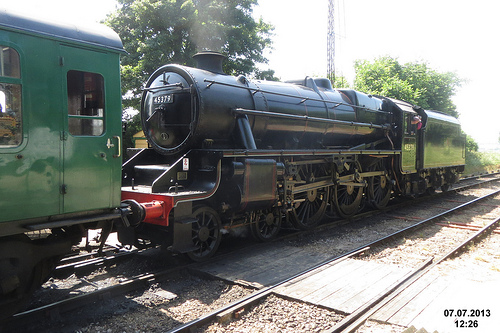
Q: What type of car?
A: Train.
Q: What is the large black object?
A: The train engine.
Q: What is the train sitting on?
A: A long train track.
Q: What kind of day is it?
A: A bright and sunny day.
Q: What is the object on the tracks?
A: A train.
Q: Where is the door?
A: On the side of the train.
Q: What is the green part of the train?
A: A train car.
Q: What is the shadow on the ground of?
A: The train.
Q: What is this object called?
A: A train.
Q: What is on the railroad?
A: A locomotive.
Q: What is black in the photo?
A: The engine.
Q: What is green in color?
A: Passenger car.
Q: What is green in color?
A: The door.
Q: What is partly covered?
A: Railroad.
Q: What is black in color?
A: The roof.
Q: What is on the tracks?
A: A train.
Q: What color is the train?
A: Black and green.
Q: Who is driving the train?
A: A person.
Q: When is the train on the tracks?
A: Now.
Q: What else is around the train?
A: Trees.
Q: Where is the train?
A: On the tracks.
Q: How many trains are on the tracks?
A: One.